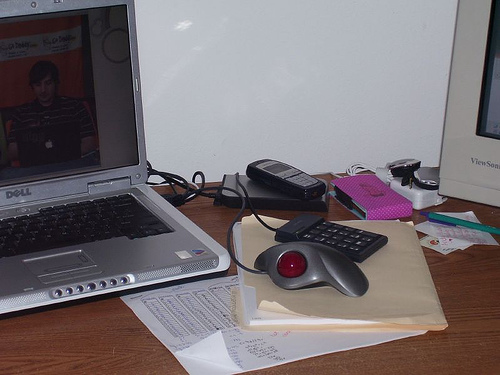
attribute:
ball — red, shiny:
[276, 250, 311, 283]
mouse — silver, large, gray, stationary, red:
[260, 234, 368, 303]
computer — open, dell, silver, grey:
[2, 5, 235, 315]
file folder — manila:
[233, 209, 449, 372]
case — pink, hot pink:
[335, 177, 396, 215]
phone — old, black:
[248, 155, 320, 204]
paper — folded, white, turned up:
[166, 316, 259, 374]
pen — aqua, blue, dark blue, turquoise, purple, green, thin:
[420, 204, 499, 240]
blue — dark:
[420, 210, 428, 222]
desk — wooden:
[7, 188, 499, 372]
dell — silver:
[5, 174, 75, 210]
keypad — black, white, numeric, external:
[276, 208, 380, 261]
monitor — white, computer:
[445, 1, 499, 226]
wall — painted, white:
[152, 3, 410, 145]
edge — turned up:
[170, 333, 252, 373]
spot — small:
[177, 14, 192, 42]